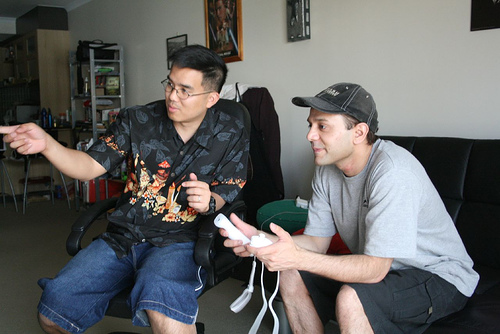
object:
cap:
[291, 82, 380, 132]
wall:
[71, 0, 500, 199]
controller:
[213, 212, 254, 257]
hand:
[219, 212, 256, 257]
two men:
[0, 44, 479, 333]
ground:
[0, 195, 335, 333]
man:
[0, 44, 249, 333]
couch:
[331, 134, 499, 333]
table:
[1, 126, 75, 196]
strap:
[230, 260, 257, 313]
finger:
[269, 222, 292, 242]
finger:
[229, 213, 256, 233]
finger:
[16, 122, 34, 133]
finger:
[189, 172, 197, 180]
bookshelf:
[68, 43, 127, 202]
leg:
[331, 285, 375, 334]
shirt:
[85, 99, 252, 259]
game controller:
[250, 232, 272, 248]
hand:
[244, 222, 303, 272]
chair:
[66, 86, 284, 334]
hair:
[167, 42, 228, 94]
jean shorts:
[37, 233, 206, 333]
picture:
[286, 0, 312, 42]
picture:
[204, 0, 243, 63]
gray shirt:
[303, 138, 480, 298]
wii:
[213, 212, 287, 334]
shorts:
[296, 254, 468, 334]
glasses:
[160, 79, 214, 100]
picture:
[165, 34, 187, 69]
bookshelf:
[0, 29, 71, 198]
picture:
[470, 0, 498, 32]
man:
[218, 82, 480, 334]